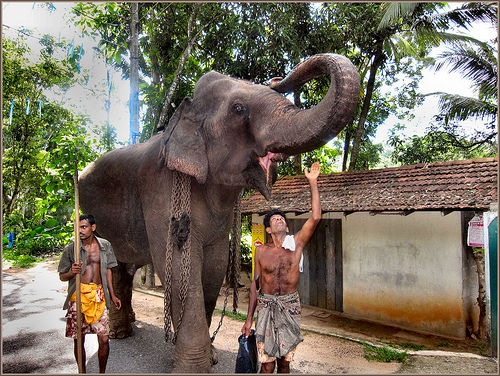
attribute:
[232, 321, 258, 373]
bag — blue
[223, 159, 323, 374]
man — skinny 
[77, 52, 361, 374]
elephant — large grey indian, overhead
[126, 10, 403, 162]
tree — many bushy green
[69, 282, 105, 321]
yellow material — yellow 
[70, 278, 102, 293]
waist — man's 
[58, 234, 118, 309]
green shirt — green 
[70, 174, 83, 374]
walking stick — walking 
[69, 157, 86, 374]
pole — long, wooden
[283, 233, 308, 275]
shirt — white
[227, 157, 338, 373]
man — man's 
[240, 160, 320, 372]
man — bare chested 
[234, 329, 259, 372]
bag — black 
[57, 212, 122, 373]
man —  two 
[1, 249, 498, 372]
path — flat tan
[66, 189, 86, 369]
pole — large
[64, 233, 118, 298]
shirt — un buttoned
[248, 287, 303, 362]
shirt — dirty grey